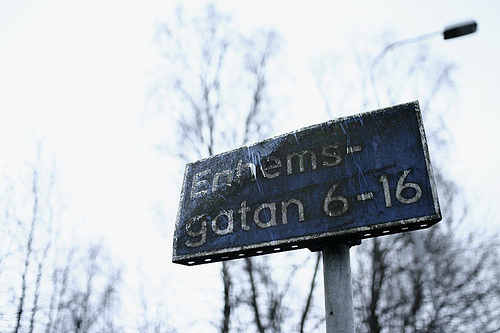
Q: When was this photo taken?
A: Daytime.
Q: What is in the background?
A: Trees.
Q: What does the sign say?
A: Enhems-gatan 6-16.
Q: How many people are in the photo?
A: None.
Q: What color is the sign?
A: Blue.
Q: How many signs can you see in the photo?
A: 1.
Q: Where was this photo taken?
A: At a street intersection.